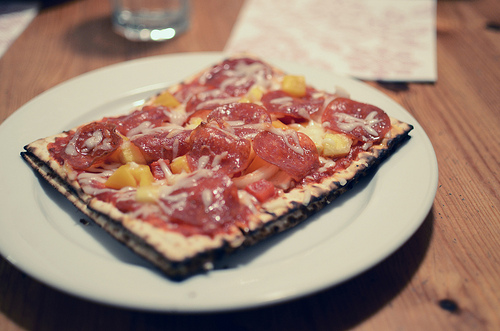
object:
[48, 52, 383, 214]
pepperoni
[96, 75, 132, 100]
plate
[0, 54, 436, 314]
plate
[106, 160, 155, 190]
cheese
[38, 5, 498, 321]
table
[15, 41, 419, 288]
flat bread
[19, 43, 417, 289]
flatbread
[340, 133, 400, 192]
bread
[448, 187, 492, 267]
table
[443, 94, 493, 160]
color brown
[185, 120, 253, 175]
topping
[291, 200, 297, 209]
black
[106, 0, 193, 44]
glass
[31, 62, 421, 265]
pizza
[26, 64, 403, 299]
dish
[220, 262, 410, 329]
shadow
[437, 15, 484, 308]
table